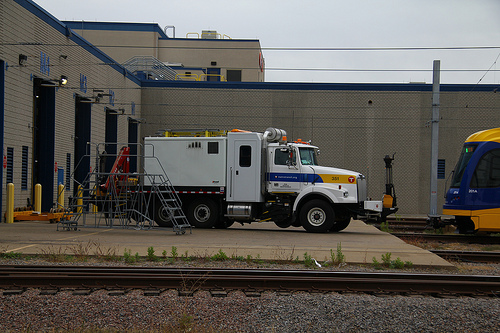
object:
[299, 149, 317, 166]
windshield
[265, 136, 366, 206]
cab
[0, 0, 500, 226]
building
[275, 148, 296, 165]
window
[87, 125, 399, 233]
truck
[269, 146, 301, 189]
passenger door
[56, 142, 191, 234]
stair case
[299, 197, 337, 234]
tire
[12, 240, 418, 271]
weeds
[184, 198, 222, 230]
wheel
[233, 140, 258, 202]
door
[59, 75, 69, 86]
light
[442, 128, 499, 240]
train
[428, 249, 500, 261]
track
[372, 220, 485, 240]
track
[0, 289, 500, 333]
gravel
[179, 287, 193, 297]
board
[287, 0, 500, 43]
sky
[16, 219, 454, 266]
road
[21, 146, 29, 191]
vent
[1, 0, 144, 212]
wall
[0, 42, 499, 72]
power lines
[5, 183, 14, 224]
pole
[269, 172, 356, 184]
stripe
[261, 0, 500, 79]
clouds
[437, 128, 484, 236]
front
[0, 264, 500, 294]
rails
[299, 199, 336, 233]
wheel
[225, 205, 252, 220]
gas tank